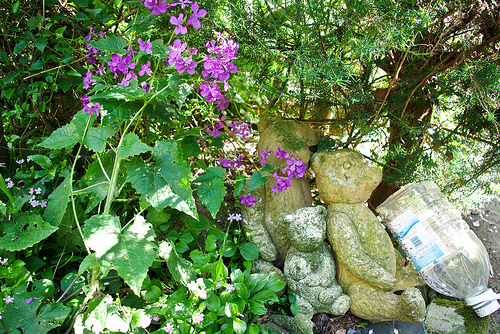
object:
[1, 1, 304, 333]
plant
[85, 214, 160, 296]
leaf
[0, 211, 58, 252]
leaf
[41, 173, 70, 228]
leaf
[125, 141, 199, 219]
leaf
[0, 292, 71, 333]
leaf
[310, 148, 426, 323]
bear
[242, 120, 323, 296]
bear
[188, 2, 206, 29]
flower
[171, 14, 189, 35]
flower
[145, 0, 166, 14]
flower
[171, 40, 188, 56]
flower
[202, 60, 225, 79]
flower